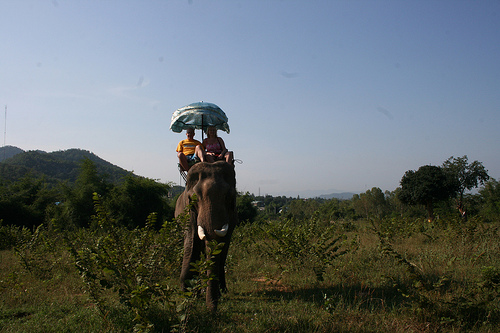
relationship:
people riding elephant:
[168, 126, 241, 174] [154, 136, 261, 325]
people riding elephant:
[168, 126, 241, 174] [159, 178, 255, 311]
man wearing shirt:
[168, 125, 208, 164] [179, 152, 203, 161]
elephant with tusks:
[166, 159, 253, 327] [188, 210, 233, 244]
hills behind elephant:
[2, 136, 164, 240] [165, 172, 257, 302]